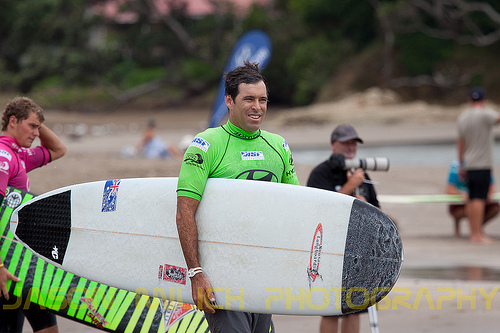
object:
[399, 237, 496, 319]
beach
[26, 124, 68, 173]
arm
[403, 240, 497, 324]
sand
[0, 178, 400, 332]
surfboard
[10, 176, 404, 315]
surfboard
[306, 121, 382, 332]
photographer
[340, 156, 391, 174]
camera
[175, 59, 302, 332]
man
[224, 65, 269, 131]
head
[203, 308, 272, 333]
shorts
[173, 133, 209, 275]
arm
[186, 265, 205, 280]
wrist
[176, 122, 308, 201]
shirt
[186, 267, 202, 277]
watch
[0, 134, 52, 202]
shirt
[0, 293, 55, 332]
shorts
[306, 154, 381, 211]
shirt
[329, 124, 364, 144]
cap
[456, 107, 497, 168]
shirt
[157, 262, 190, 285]
symbol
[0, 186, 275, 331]
surfboard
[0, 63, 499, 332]
people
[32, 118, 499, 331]
beach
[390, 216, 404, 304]
end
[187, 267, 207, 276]
bracelet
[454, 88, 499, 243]
person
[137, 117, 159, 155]
person